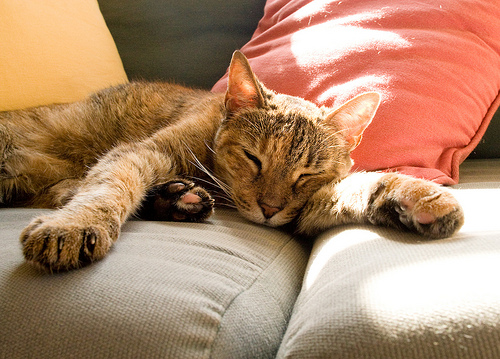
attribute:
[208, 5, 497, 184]
pillow — here, small, red, pink, peach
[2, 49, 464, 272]
cat — brown, sleeping, relaxed, striped, pink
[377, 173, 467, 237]
paw — here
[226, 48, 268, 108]
ear — here, pointy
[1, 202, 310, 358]
cushion — here, grey, brown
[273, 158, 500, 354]
cushion — grey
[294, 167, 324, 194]
right eye — closed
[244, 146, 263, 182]
left eye — open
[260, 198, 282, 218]
nose — small, pink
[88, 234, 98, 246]
claw — small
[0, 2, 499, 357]
couch — grey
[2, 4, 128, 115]
pillow — orange, yellow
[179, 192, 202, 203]
toe — pink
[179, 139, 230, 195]
whisker — white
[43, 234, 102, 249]
nails — sharp